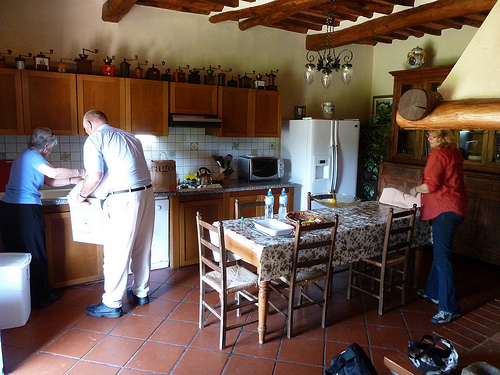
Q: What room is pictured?
A: It is a kitchen.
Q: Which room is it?
A: It is a kitchen.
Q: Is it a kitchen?
A: Yes, it is a kitchen.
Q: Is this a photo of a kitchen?
A: Yes, it is showing a kitchen.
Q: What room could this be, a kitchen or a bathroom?
A: It is a kitchen.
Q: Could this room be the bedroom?
A: No, it is the kitchen.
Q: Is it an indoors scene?
A: Yes, it is indoors.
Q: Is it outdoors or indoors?
A: It is indoors.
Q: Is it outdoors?
A: No, it is indoors.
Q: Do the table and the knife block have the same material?
A: Yes, both the table and the knife block are made of wood.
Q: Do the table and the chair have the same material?
A: Yes, both the table and the chair are made of wood.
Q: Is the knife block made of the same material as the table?
A: Yes, both the knife block and the table are made of wood.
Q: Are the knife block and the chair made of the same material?
A: Yes, both the knife block and the chair are made of wood.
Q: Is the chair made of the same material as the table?
A: Yes, both the chair and the table are made of wood.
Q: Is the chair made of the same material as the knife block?
A: Yes, both the chair and the knife block are made of wood.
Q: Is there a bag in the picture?
A: Yes, there is a bag.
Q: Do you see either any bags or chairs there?
A: Yes, there is a bag.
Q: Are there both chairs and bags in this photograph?
A: Yes, there are both a bag and a chair.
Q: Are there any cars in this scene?
A: No, there are no cars.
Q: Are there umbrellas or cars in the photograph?
A: No, there are no cars or umbrellas.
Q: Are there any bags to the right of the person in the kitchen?
A: Yes, there is a bag to the right of the person.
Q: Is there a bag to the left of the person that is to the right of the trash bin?
A: No, the bag is to the right of the person.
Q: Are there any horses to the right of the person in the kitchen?
A: No, there is a bag to the right of the person.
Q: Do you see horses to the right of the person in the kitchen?
A: No, there is a bag to the right of the person.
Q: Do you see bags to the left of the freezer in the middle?
A: Yes, there is a bag to the left of the refrigerator.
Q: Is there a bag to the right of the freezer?
A: No, the bag is to the left of the freezer.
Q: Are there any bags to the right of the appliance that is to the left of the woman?
A: No, the bag is to the left of the freezer.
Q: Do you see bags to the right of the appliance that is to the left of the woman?
A: No, the bag is to the left of the freezer.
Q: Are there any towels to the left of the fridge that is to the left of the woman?
A: No, there is a bag to the left of the fridge.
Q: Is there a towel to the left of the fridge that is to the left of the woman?
A: No, there is a bag to the left of the fridge.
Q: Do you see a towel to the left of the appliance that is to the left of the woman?
A: No, there is a bag to the left of the fridge.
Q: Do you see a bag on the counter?
A: Yes, there is a bag on the counter.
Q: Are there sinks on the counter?
A: No, there is a bag on the counter.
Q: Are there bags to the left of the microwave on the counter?
A: Yes, there is a bag to the left of the microwave.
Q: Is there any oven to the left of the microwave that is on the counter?
A: No, there is a bag to the left of the microwave.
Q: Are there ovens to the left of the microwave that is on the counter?
A: No, there is a bag to the left of the microwave.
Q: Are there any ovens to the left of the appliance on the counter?
A: No, there is a bag to the left of the microwave.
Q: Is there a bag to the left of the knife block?
A: Yes, there is a bag to the left of the knife block.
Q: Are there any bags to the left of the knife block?
A: Yes, there is a bag to the left of the knife block.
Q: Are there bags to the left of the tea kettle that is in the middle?
A: Yes, there is a bag to the left of the tea kettle.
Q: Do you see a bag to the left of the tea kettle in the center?
A: Yes, there is a bag to the left of the tea kettle.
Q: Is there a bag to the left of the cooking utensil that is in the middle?
A: Yes, there is a bag to the left of the tea kettle.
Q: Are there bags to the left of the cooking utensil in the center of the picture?
A: Yes, there is a bag to the left of the tea kettle.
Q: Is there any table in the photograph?
A: Yes, there is a table.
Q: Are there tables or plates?
A: Yes, there is a table.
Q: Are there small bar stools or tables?
A: Yes, there is a small table.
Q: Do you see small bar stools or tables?
A: Yes, there is a small table.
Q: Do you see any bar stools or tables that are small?
A: Yes, the table is small.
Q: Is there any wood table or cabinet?
A: Yes, there is a wood table.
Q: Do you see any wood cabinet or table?
A: Yes, there is a wood table.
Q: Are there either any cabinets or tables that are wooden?
A: Yes, the table is wooden.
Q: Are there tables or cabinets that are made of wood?
A: Yes, the table is made of wood.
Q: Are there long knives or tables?
A: Yes, there is a long table.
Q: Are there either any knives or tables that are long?
A: Yes, the table is long.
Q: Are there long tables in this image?
A: Yes, there is a long table.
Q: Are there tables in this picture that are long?
A: Yes, there is a table that is long.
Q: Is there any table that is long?
A: Yes, there is a table that is long.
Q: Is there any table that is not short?
A: Yes, there is a long table.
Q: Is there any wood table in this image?
A: Yes, there is a wood table.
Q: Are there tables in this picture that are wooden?
A: Yes, there is a table that is wooden.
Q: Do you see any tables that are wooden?
A: Yes, there is a table that is wooden.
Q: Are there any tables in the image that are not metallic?
A: Yes, there is a wooden table.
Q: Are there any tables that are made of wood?
A: Yes, there is a table that is made of wood.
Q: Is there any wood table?
A: Yes, there is a table that is made of wood.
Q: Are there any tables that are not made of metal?
A: Yes, there is a table that is made of wood.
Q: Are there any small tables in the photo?
A: Yes, there is a small table.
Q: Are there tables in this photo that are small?
A: Yes, there is a table that is small.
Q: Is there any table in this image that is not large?
A: Yes, there is a small table.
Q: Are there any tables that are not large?
A: Yes, there is a small table.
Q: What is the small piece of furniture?
A: The piece of furniture is a table.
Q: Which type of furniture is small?
A: The furniture is a table.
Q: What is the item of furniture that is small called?
A: The piece of furniture is a table.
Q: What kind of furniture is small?
A: The furniture is a table.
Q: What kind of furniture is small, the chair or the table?
A: The table is small.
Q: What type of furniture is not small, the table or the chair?
A: The chair is not small.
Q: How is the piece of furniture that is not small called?
A: The piece of furniture is a chair.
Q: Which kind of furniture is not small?
A: The furniture is a chair.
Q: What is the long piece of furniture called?
A: The piece of furniture is a table.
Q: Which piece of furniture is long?
A: The piece of furniture is a table.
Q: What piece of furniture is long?
A: The piece of furniture is a table.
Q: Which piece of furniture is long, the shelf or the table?
A: The table is long.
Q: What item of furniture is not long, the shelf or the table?
A: The shelf is not long.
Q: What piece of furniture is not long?
A: The piece of furniture is a shelf.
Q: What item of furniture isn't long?
A: The piece of furniture is a shelf.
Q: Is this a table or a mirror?
A: This is a table.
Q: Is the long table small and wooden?
A: Yes, the table is small and wooden.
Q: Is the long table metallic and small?
A: No, the table is small but wooden.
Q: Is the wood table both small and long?
A: Yes, the table is small and long.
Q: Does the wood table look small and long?
A: Yes, the table is small and long.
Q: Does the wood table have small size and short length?
A: No, the table is small but long.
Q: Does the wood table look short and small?
A: No, the table is small but long.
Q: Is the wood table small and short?
A: No, the table is small but long.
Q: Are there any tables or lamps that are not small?
A: No, there is a table but it is small.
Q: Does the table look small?
A: Yes, the table is small.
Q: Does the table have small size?
A: Yes, the table is small.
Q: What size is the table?
A: The table is small.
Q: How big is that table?
A: The table is small.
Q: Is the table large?
A: No, the table is small.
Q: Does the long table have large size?
A: No, the table is small.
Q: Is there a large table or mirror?
A: No, there is a table but it is small.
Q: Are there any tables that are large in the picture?
A: No, there is a table but it is small.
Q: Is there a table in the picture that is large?
A: No, there is a table but it is small.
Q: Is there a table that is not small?
A: No, there is a table but it is small.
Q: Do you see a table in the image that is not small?
A: No, there is a table but it is small.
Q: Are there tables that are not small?
A: No, there is a table but it is small.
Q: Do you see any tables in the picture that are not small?
A: No, there is a table but it is small.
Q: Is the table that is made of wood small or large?
A: The table is small.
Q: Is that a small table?
A: Yes, that is a small table.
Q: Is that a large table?
A: No, that is a small table.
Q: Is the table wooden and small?
A: Yes, the table is wooden and small.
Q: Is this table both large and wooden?
A: No, the table is wooden but small.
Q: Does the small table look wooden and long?
A: Yes, the table is wooden and long.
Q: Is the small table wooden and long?
A: Yes, the table is wooden and long.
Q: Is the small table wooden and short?
A: No, the table is wooden but long.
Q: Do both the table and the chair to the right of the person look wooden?
A: Yes, both the table and the chair are wooden.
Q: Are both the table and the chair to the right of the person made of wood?
A: Yes, both the table and the chair are made of wood.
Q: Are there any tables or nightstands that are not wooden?
A: No, there is a table but it is wooden.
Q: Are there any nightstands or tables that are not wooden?
A: No, there is a table but it is wooden.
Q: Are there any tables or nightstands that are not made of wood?
A: No, there is a table but it is made of wood.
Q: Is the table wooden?
A: Yes, the table is wooden.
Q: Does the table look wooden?
A: Yes, the table is wooden.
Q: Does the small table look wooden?
A: Yes, the table is wooden.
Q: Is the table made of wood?
A: Yes, the table is made of wood.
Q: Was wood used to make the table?
A: Yes, the table is made of wood.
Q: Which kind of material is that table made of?
A: The table is made of wood.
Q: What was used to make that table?
A: The table is made of wood.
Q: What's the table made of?
A: The table is made of wood.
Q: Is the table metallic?
A: No, the table is wooden.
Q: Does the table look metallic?
A: No, the table is wooden.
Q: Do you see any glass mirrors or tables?
A: No, there is a table but it is wooden.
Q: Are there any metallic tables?
A: No, there is a table but it is wooden.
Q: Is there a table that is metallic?
A: No, there is a table but it is wooden.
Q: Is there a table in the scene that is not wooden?
A: No, there is a table but it is wooden.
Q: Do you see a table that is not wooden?
A: No, there is a table but it is wooden.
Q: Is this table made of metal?
A: No, the table is made of wood.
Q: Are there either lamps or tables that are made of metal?
A: No, there is a table but it is made of wood.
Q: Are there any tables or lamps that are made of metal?
A: No, there is a table but it is made of wood.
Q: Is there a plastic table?
A: No, there is a table but it is made of wood.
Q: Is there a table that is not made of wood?
A: No, there is a table but it is made of wood.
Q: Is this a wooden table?
A: Yes, this is a wooden table.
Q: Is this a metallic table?
A: No, this is a wooden table.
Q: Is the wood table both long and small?
A: Yes, the table is long and small.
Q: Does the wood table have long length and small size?
A: Yes, the table is long and small.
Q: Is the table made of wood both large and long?
A: No, the table is long but small.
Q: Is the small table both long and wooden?
A: Yes, the table is long and wooden.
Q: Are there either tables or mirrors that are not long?
A: No, there is a table but it is long.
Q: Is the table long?
A: Yes, the table is long.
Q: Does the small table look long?
A: Yes, the table is long.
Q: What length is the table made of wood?
A: The table is long.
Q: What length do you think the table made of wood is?
A: The table is long.